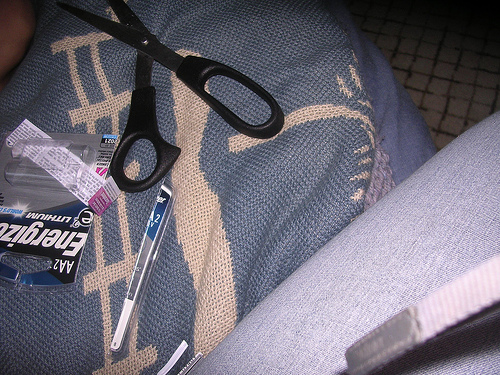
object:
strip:
[111, 183, 178, 348]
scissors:
[50, 0, 283, 192]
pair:
[62, 1, 285, 193]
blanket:
[0, 0, 372, 374]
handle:
[109, 86, 184, 192]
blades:
[51, 0, 140, 42]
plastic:
[0, 130, 117, 294]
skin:
[0, 0, 36, 71]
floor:
[350, 0, 499, 150]